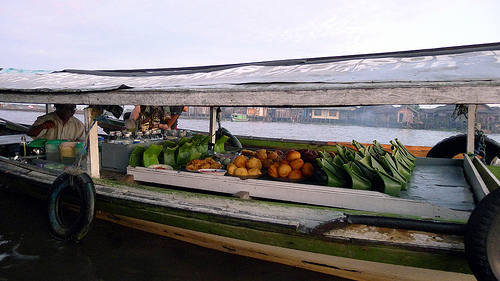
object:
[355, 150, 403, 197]
leaf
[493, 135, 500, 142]
water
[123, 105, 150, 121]
people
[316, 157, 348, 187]
bags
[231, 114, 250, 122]
boat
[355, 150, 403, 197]
bags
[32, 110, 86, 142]
shirt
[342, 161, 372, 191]
leaf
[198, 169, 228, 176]
bowl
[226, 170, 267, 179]
bowl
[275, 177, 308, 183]
bowl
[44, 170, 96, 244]
ring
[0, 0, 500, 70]
sky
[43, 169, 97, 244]
tires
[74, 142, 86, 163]
container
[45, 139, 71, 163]
container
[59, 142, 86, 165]
container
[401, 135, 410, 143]
water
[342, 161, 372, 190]
bags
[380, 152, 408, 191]
leaf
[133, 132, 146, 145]
bottles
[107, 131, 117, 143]
bottles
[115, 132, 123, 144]
bottles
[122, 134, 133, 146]
bottles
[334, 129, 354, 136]
water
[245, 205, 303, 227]
wood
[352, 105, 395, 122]
building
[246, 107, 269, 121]
building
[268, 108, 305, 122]
building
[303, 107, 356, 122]
building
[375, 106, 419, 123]
building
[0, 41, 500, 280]
boat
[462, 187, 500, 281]
tire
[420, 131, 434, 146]
water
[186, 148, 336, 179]
fruit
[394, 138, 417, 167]
leaf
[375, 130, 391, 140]
water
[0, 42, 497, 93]
roof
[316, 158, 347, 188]
leaf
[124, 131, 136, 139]
bottles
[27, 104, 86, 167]
man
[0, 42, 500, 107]
boat canopy